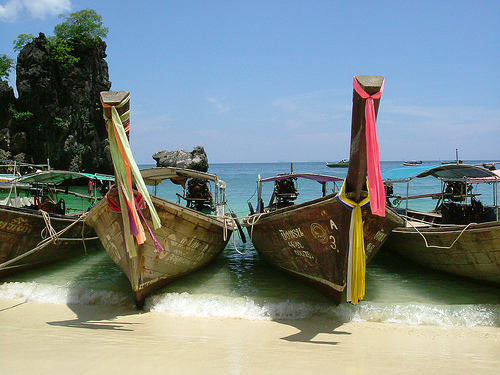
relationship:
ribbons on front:
[335, 75, 386, 305] [304, 75, 401, 304]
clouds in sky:
[0, 0, 492, 157] [2, 0, 496, 160]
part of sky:
[251, 19, 311, 96] [2, 0, 496, 160]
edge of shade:
[280, 334, 339, 345] [271, 313, 353, 342]